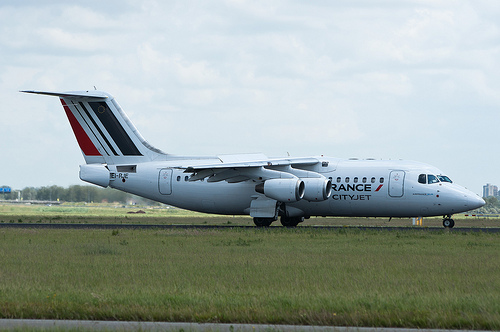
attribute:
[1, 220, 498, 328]
grass — tall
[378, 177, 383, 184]
window — passenger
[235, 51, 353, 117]
clouds — white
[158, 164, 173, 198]
door — white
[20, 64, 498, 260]
airplane — white, blue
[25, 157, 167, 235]
trees — distant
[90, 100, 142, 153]
stripe — black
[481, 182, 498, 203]
building — tall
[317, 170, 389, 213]
writing — black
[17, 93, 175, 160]
tail — red